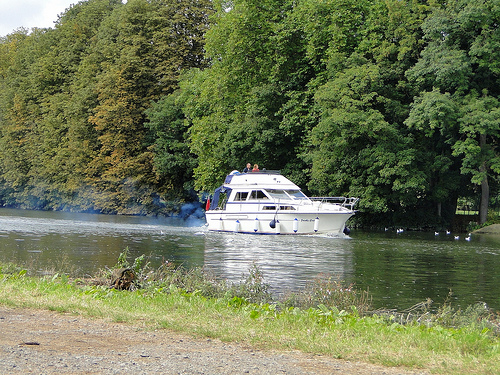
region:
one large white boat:
[198, 161, 356, 240]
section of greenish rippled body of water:
[14, 219, 180, 247]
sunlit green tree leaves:
[199, 29, 469, 148]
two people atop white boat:
[233, 160, 268, 233]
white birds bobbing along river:
[371, 222, 477, 249]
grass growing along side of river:
[105, 255, 374, 333]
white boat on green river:
[28, 133, 426, 269]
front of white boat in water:
[319, 200, 356, 237]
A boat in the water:
[197, 162, 365, 239]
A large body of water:
[22, 220, 149, 255]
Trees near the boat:
[13, 25, 483, 155]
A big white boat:
[210, 162, 360, 236]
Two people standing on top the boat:
[243, 162, 258, 171]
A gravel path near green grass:
[20, 322, 125, 372]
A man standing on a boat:
[241, 162, 251, 172]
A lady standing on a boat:
[253, 165, 259, 170]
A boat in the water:
[203, 165, 363, 238]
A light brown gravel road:
[8, 322, 114, 369]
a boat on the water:
[51, 70, 446, 312]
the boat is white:
[169, 139, 379, 237]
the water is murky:
[31, 217, 465, 319]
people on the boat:
[225, 148, 274, 178]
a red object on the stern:
[203, 179, 215, 221]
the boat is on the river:
[133, 154, 409, 273]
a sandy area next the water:
[7, 284, 377, 374]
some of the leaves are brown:
[38, 49, 178, 209]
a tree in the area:
[412, 94, 499, 257]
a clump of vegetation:
[47, 251, 165, 313]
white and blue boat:
[209, 176, 336, 241]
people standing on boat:
[242, 154, 263, 179]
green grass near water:
[94, 266, 426, 362]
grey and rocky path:
[28, 309, 176, 374]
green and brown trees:
[1, 21, 251, 198]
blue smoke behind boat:
[167, 194, 212, 233]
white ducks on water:
[377, 219, 470, 255]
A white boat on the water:
[203, 157, 360, 237]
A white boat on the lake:
[199, 152, 355, 246]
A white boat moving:
[206, 160, 358, 251]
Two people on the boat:
[236, 150, 263, 170]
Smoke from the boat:
[176, 199, 204, 226]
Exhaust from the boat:
[171, 198, 204, 227]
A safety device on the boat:
[311, 215, 323, 232]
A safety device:
[288, 216, 300, 232]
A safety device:
[251, 214, 260, 235]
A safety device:
[233, 217, 244, 233]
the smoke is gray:
[68, 174, 219, 229]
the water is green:
[60, 225, 211, 262]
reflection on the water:
[227, 229, 314, 292]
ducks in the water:
[380, 222, 477, 252]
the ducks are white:
[385, 216, 483, 254]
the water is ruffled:
[32, 213, 199, 248]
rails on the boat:
[279, 192, 354, 219]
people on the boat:
[240, 160, 272, 177]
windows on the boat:
[235, 187, 311, 202]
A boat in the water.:
[192, 156, 347, 248]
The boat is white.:
[198, 168, 333, 243]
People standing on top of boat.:
[238, 158, 263, 178]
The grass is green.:
[187, 290, 415, 359]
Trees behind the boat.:
[206, 13, 419, 212]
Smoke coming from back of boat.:
[147, 192, 214, 230]